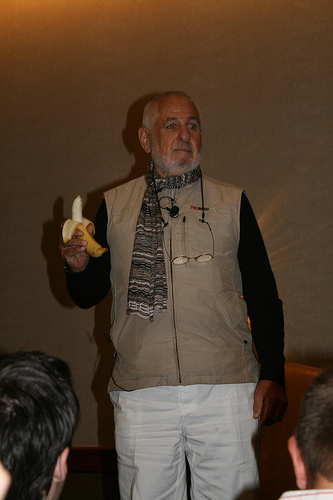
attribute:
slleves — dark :
[242, 191, 281, 378]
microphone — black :
[157, 195, 182, 222]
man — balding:
[54, 83, 291, 499]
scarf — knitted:
[128, 176, 166, 319]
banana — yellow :
[69, 195, 85, 221]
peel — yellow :
[60, 221, 105, 254]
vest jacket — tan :
[102, 174, 258, 392]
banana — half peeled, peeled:
[56, 194, 108, 259]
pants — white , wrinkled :
[108, 381, 262, 498]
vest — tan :
[96, 177, 258, 380]